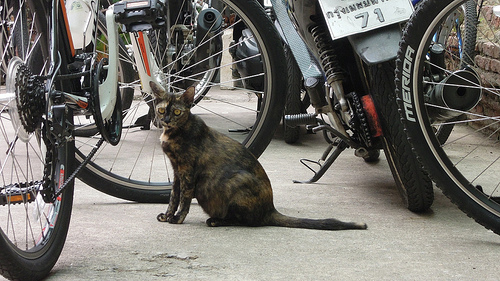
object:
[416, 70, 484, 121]
exhaust pipe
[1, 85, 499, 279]
road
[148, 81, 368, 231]
cat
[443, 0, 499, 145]
wall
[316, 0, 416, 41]
plate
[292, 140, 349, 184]
kick stand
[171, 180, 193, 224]
leg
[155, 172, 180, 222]
leg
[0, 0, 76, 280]
tire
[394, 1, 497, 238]
bike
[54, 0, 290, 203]
bike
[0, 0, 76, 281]
bike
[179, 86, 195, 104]
ears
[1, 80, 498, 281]
sidewalk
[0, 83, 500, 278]
concrete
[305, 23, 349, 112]
pipe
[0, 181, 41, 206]
pedal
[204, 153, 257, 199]
brownfur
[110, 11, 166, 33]
pedal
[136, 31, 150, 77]
reflector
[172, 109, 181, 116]
cat's eye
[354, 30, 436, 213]
tire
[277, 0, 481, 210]
motorcycle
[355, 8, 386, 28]
71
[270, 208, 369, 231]
cat tail